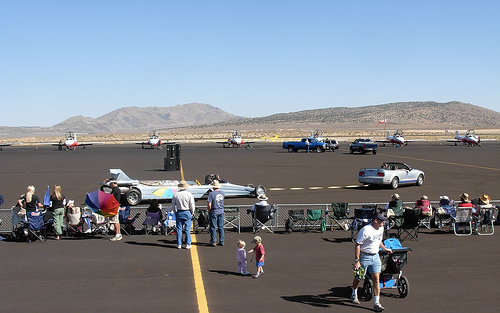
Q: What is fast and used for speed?
A: A race car.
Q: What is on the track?
A: A race car.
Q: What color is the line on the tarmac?
A: Yellow.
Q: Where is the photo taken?
A: A large Tarmac near the mountains.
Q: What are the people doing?
A: Watching cars and planes.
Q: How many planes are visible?
A: Around 5.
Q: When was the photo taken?
A: Day time.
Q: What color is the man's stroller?
A: Blue.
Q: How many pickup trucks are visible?
A: 2.